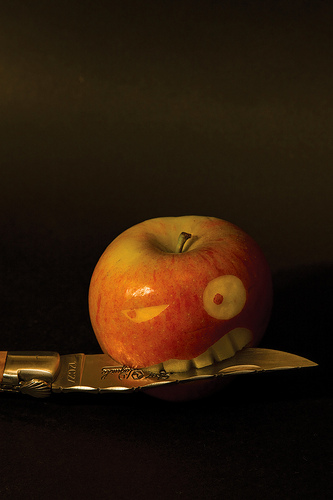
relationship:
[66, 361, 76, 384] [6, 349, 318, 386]
number on blade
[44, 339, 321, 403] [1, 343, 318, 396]
blade attacthed to pocket knife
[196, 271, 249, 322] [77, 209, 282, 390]
eye on apple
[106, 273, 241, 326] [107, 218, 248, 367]
eyes carved into apple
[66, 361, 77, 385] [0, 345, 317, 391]
writing on knife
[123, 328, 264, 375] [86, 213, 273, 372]
teeth carved in apple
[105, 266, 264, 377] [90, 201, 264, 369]
face carved in apple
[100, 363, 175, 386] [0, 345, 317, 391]
carvings on knife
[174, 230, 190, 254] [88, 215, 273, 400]
stem of apple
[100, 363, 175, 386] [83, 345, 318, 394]
carvings in blade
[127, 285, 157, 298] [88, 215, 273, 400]
light reflection on apple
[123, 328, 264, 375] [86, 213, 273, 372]
teeth on apple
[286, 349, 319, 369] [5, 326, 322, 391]
knife point on knife